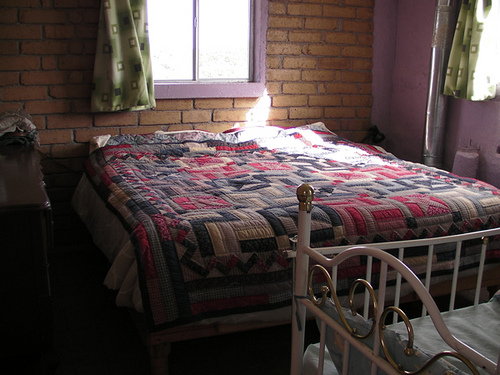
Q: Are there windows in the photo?
A: Yes, there is a window.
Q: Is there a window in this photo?
A: Yes, there is a window.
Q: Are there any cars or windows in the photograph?
A: Yes, there is a window.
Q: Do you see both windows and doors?
A: No, there is a window but no doors.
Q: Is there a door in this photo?
A: No, there are no doors.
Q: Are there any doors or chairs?
A: No, there are no doors or chairs.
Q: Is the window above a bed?
A: Yes, the window is above a bed.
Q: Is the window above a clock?
A: No, the window is above a bed.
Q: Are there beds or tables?
A: Yes, there is a bed.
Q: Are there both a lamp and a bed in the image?
A: No, there is a bed but no lamps.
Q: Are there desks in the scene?
A: No, there are no desks.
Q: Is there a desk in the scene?
A: No, there are no desks.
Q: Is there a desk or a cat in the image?
A: No, there are no desks or cats.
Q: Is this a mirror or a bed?
A: This is a bed.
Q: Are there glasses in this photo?
A: No, there are no glasses.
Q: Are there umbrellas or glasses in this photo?
A: No, there are no glasses or umbrellas.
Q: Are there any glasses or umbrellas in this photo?
A: No, there are no glasses or umbrellas.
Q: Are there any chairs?
A: No, there are no chairs.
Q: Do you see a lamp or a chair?
A: No, there are no chairs or lamps.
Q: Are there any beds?
A: Yes, there is a bed.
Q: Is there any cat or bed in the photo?
A: Yes, there is a bed.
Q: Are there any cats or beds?
A: Yes, there is a bed.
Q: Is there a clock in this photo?
A: No, there are no clocks.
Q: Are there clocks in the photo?
A: No, there are no clocks.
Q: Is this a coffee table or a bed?
A: This is a bed.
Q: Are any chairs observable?
A: No, there are no chairs.